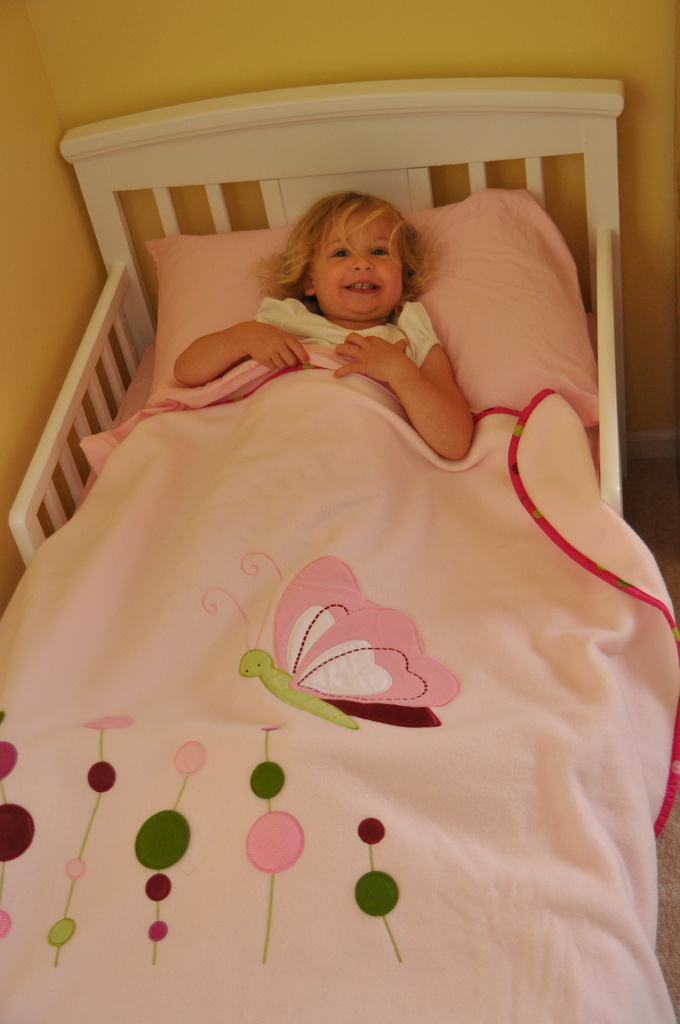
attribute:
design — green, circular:
[352, 869, 400, 917]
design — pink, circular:
[244, 808, 307, 876]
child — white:
[169, 189, 476, 465]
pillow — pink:
[144, 185, 601, 442]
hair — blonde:
[263, 182, 429, 279]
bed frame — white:
[7, 70, 638, 578]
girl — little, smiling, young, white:
[169, 189, 474, 469]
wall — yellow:
[26, 0, 657, 440]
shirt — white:
[255, 296, 444, 371]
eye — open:
[327, 243, 354, 261]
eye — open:
[365, 244, 392, 256]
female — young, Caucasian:
[161, 174, 484, 483]